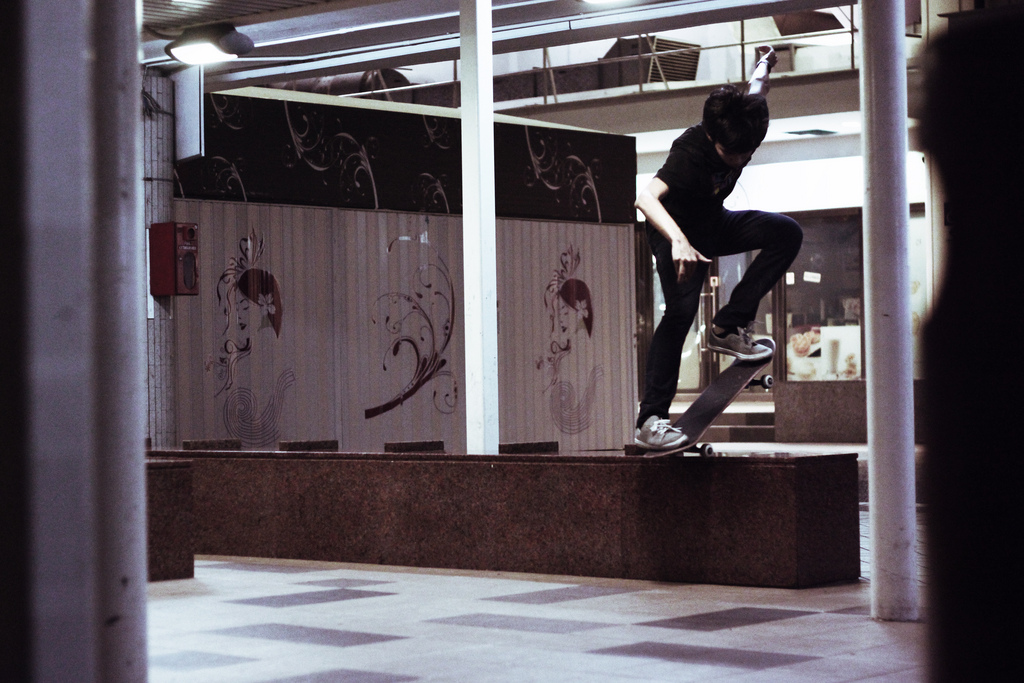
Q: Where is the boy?
A: Hallway.